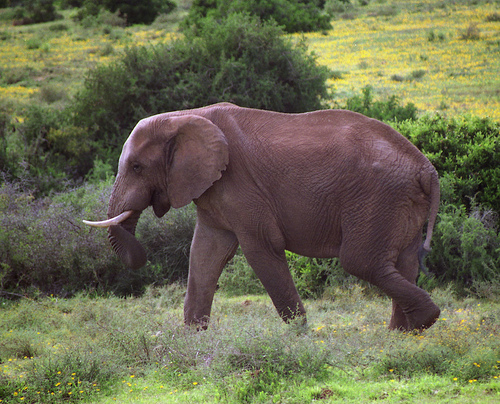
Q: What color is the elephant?
A: Gray.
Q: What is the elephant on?
A: The grass.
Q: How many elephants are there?
A: One.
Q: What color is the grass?
A: Green.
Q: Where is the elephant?
A: On the grass.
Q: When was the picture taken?
A: Daytime.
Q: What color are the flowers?
A: Yellow.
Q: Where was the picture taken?
A: On the savannah.